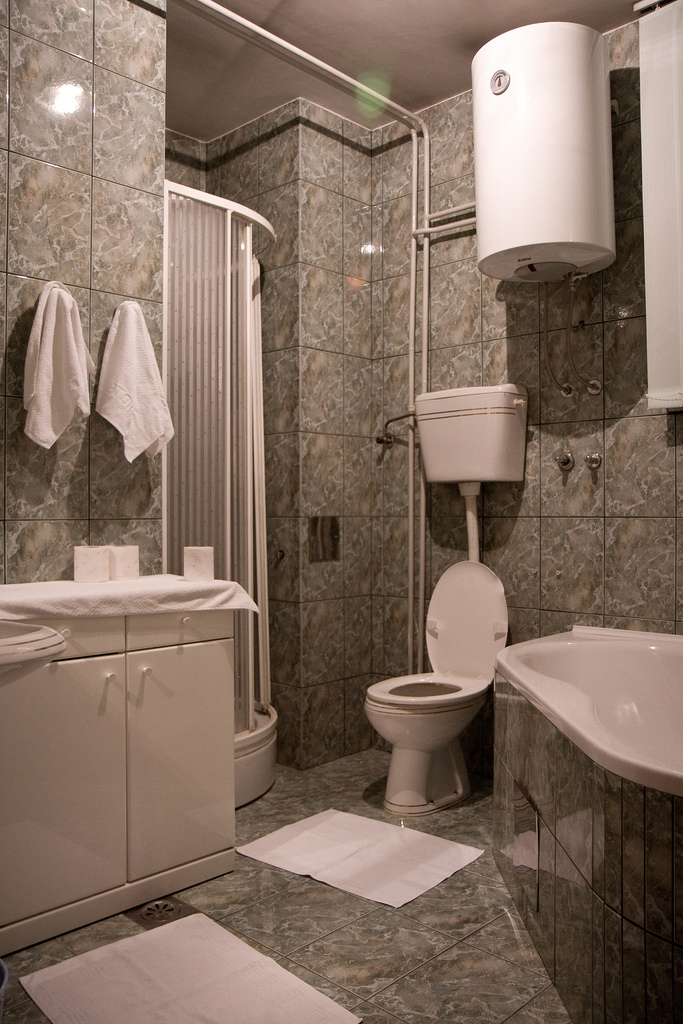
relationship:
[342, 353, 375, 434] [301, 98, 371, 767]
tile on wall